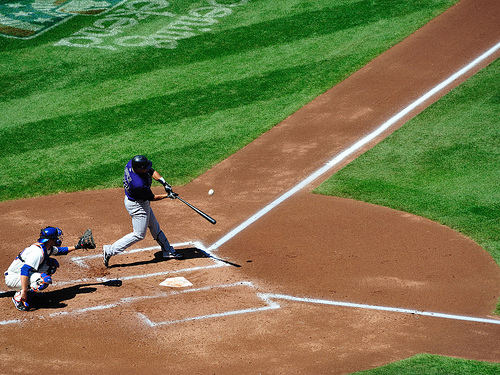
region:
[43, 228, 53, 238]
man wearing blue helmet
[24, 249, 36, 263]
man wearing white shirt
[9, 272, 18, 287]
man wearing white pants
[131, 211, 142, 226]
man wearing grey pants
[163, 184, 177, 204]
mans hands on bat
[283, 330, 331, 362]
brown dirt in field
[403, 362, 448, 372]
green grass on field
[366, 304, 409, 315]
white line on field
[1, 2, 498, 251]
green grass on field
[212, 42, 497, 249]
white line on dirt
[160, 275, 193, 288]
white surface of home plate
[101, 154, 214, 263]
player swinging baseball bat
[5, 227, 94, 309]
catcher holding mitt up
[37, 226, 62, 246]
blue helmet on head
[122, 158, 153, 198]
blue shirt of uniform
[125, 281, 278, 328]
lines indicating batter's box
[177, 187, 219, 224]
ball in front of bat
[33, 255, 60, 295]
pads on catcher's knees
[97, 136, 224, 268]
batter wearing blue jersey swinging black bat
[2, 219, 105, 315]
catcher crouching holding black mitt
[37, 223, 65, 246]
blue helmet worn by catcher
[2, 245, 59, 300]
white uniform worn by catcher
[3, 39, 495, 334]
white chalk lines in dirt baseball field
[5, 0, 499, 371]
green grassy field surrounding dirt mound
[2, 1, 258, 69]
white design with American flag motif on grass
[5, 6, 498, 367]
sunny daytime baseball gasme scene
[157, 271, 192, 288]
white baseball diamond in dirt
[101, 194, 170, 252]
gray uniform on baseball player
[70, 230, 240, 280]
this is a batter's box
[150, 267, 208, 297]
this is home plate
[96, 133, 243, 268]
he is swinging his bat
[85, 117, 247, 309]
he is swinging a baseball bat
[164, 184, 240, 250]
this is a baseball and bat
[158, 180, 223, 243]
this is a black baseball bat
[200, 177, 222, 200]
the ball is in the air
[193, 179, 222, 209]
the ball is white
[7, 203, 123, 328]
he is a catcher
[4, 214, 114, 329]
he is wearing pads and a helmet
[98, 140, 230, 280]
A person swinging a bat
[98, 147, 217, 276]
A man swinging a bat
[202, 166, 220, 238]
A white ball in the air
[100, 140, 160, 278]
A person wearing a blue shirt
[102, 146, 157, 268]
A person wearing a blue helmet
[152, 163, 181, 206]
A person wearing black gloves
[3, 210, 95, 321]
A person wearing a catcher mitt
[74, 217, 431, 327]
Chalk lines on the batting field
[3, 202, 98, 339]
A person bending knees to catch a ball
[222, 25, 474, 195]
Green grass and brown dirt on a baseball field